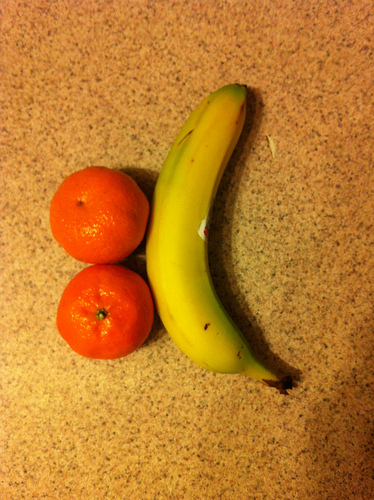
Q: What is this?
A: Fruit.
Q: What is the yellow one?
A: A banana.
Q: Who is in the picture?
A: No one.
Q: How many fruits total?
A: Three.